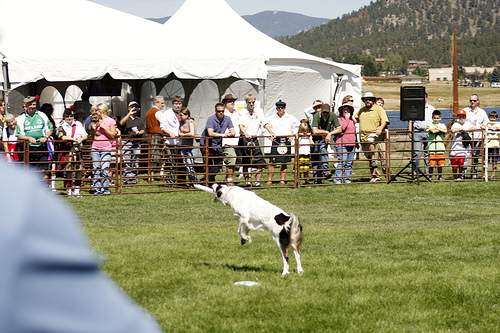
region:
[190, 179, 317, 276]
a dog catching a white frisbee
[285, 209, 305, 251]
the tail of a dog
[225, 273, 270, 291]
a white frisbee on the ground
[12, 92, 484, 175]
a crowd of people behind a fence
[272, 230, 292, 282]
the hind leg of a dog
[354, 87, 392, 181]
a man wearing a hat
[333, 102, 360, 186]
a woman wearing a hat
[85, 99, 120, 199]
a woman wearing pink holding a dog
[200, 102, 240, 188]
a man wearing sunglasses and a blue shirt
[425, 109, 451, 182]
a boy wearing a green shirt and orange shorts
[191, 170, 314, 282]
Spotted goat with single horn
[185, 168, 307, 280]
Goat charging with horn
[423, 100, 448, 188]
Boy in orange shorts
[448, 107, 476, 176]
Boy in red had and red shorts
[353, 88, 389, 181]
Man wearing yellow shirt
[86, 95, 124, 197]
Woman in pink shirt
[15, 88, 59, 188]
Man wearing gray tam o shanter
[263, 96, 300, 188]
Man wearing tam and kilt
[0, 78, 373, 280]
People watching goat jump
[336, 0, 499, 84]
Houses at bottom of mountain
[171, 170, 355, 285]
a black and white dog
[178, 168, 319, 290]
a dog catches a frisbee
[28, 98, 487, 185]
people spectate behind a fence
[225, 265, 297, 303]
a frisbee on the ground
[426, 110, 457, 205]
this boy has orange shorts on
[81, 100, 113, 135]
this woman holds her dog up to see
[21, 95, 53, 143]
this man is weraing a green and white shirt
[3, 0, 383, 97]
a white tent behind the people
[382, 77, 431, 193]
a speaker is on a pole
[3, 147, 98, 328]
a persons shoulder is in the shot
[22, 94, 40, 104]
Cap with a red pom pom on the side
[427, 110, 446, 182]
Boy in light green shirt and orange shorts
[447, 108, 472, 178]
Child in red cap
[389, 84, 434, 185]
Black speaker on 3 legged stand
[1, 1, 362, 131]
Two white cloth tents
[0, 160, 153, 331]
Arm and part of a shoulder on the left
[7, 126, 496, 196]
Brown fence on the grass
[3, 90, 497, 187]
People outside watching an event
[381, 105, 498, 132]
Small body of water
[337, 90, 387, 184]
Large couple in white hats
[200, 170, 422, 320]
the dog is jumping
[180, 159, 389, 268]
the dog caught a frisbee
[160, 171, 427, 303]
a frisbee is in the dog's mouth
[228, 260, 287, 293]
a frisbee is on the ground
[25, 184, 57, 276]
a man is in a blue jacket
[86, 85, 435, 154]
the audience is in the background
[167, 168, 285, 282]
the dog is on green grass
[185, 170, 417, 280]
the dog is black and white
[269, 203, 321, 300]
the dog has a black bottom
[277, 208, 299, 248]
the dog has a bushy tail